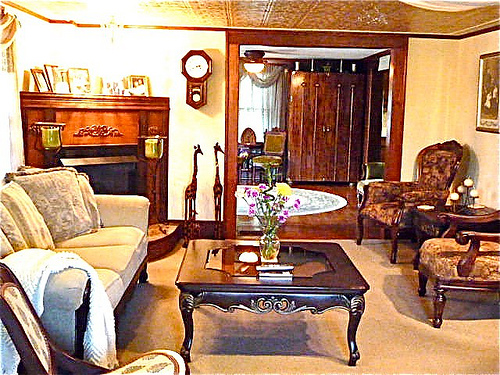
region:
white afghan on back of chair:
[0, 242, 123, 374]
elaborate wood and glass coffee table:
[170, 234, 374, 367]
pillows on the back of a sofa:
[4, 161, 96, 276]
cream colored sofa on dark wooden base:
[1, 163, 156, 355]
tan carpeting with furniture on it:
[111, 217, 491, 369]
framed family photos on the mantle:
[15, 53, 155, 100]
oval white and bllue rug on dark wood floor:
[217, 180, 348, 220]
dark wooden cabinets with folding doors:
[275, 55, 372, 185]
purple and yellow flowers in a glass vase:
[233, 176, 302, 261]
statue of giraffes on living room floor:
[178, 138, 225, 229]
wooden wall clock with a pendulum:
[180, 45, 214, 110]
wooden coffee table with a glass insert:
[174, 238, 369, 368]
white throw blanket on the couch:
[0, 245, 117, 373]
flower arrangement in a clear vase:
[233, 160, 302, 261]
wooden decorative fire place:
[17, 91, 181, 263]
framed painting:
[476, 51, 498, 135]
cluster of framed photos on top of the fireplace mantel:
[28, 63, 152, 93]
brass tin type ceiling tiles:
[8, 0, 499, 36]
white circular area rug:
[237, 183, 349, 216]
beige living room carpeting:
[114, 236, 499, 372]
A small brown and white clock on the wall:
[180, 50, 214, 109]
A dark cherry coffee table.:
[175, 236, 368, 366]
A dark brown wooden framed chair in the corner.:
[357, 135, 464, 260]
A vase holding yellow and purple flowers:
[230, 178, 305, 262]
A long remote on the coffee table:
[253, 262, 293, 274]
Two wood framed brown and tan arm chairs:
[355, 138, 499, 327]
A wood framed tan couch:
[0, 163, 150, 359]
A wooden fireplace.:
[18, 91, 171, 224]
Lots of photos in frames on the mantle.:
[26, 62, 149, 102]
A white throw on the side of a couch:
[2, 245, 118, 373]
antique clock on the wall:
[180, 50, 212, 108]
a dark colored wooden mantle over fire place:
[19, 91, 171, 226]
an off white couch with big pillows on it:
[1, 165, 150, 359]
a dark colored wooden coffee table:
[176, 237, 369, 367]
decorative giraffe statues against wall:
[183, 143, 225, 248]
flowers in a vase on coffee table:
[235, 182, 302, 262]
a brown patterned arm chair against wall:
[355, 140, 472, 263]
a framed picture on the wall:
[475, 50, 498, 132]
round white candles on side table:
[447, 176, 483, 215]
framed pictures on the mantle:
[31, 63, 152, 95]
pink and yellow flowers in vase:
[242, 180, 294, 262]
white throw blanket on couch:
[1, 245, 116, 369]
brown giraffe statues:
[189, 140, 226, 235]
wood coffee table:
[174, 235, 371, 365]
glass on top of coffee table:
[206, 240, 336, 282]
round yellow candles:
[444, 175, 485, 213]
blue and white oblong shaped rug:
[238, 178, 346, 218]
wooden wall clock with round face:
[179, 48, 214, 110]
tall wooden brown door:
[278, 63, 373, 185]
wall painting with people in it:
[475, 53, 499, 134]